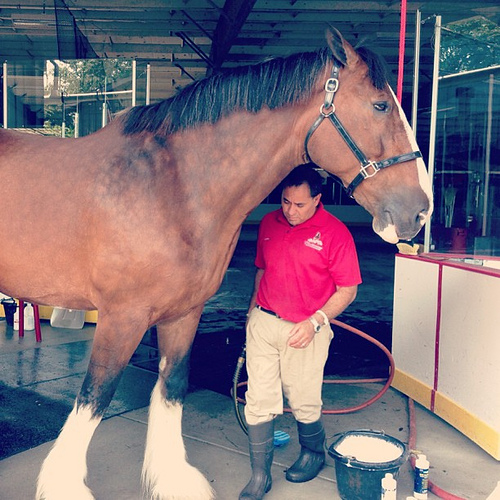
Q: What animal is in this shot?
A: A horse.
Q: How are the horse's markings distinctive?
A: The horse is brown with white feet, and a little bit of black.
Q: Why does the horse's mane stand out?
A: It is black.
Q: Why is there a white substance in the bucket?
A: This is a bucket of soapy water.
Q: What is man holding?
A: Horse.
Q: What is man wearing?
A: Red shirt.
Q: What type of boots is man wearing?
A: Rubber.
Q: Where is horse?
A: In barn.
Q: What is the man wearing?
A: Red shirt.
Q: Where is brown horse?
A: Stable.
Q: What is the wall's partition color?
A: White, red and yellow.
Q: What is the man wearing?
A: Khaki pants.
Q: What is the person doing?
A: Taking care of a horse.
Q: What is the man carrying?
A: A hose.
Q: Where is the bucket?
A: On the ground.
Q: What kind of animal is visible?
A: A horse.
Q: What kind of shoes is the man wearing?
A: Rubber boots.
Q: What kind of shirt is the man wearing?
A: A red polo shirt.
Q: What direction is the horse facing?
A: To the right.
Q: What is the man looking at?
A: The horse's feet.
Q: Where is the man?
A: Underneath the horse's neck.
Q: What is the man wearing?
A: A red shirt and tan pants.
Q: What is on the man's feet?
A: Boots.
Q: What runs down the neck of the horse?
A: A mane.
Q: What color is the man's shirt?
A: Red.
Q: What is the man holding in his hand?
A: A hose.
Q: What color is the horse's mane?
A: Black.